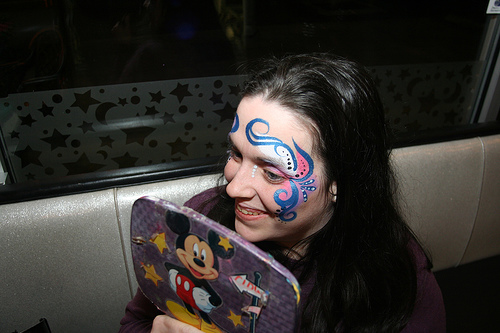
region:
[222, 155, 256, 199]
the nose of the woman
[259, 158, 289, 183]
the eye of the woman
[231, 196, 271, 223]
the mouth of the woman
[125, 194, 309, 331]
a mirror in the woman's hand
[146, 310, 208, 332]
the hand of the woman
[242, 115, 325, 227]
face paint on the woman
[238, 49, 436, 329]
the hair of the woman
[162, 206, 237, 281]
the head of Mickey Mouse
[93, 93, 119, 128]
a black moon cutout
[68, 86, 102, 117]
a black star cutout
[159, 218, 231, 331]
a cartoon character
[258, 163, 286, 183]
a woman's left eye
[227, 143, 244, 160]
a woman's left eye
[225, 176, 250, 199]
a woman's nose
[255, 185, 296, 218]
a woman's cheek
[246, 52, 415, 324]
a woman's black long hair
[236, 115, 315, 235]
paint i her face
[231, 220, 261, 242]
a woman's chin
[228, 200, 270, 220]
a woman's smile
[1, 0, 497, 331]
it is a clear picture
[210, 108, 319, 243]
A woman prepares to be a clown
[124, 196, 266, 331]
Mickey Mouse adorns this mirror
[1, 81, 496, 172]
A night time skyscape outside of the window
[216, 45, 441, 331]
A young woman with black hair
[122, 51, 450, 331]
This woman is checking out her face paint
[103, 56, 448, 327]
Black hair flows from her head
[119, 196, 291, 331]
The mirror is purple with yellow stars and a famous rodent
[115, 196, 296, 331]
The white arrow is pointing at Mickey Mouse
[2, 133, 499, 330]
The cushion rests against the side of the room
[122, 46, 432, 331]
The woman is delighted at her face paint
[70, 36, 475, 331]
women with colorful face paint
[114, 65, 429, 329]
women with blue, white and pink face paint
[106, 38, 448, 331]
woman smiling with mirror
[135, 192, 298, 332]
purple mickey mouse mirror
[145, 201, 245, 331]
disney character mickey mouse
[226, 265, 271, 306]
white arrow with pink text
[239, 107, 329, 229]
blue, white and pink face paint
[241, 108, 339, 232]
beautiful swirly face paint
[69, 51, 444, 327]
black haired woman with purple shirt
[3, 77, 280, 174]
stars, moon and planets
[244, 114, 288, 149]
Girl has blue wavy makeup on her forehead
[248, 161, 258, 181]
Four white dots painted on side of girl's nose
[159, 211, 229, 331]
Picture of mickey mouse with purple backgroun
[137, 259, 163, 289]
Picture of a small gold star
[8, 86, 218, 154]
White privacy screen with stars, moons, and circles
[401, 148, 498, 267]
Padded cushions for back comfort and support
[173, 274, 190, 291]
Two big white buttons on mickey's shorts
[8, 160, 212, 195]
Section of upholstered back board that supports cushions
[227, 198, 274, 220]
Young lady is smiling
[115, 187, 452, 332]
Girl is wearing a purple shirt